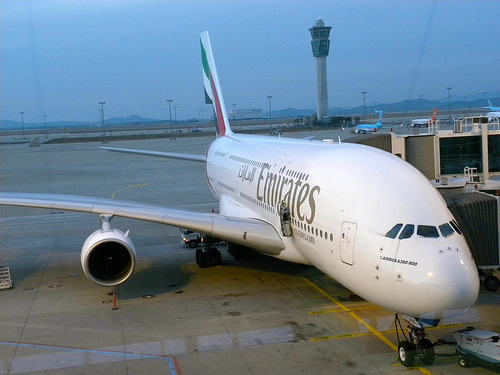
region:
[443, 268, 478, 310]
nose of the airplane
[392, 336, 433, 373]
wheels in front of airplane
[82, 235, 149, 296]
engine on the airplane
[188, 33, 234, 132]
tail part of airplane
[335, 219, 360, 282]
door on the airplane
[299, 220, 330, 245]
windows on side of plane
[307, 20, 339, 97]
the air traffic tower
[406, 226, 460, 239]
windows in front of plane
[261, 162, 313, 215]
name of aircraft carrier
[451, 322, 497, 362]
cart for transporting luggage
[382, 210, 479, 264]
five dark air plane windows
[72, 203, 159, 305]
white air plane engine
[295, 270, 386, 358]
yellow painted lines on the grown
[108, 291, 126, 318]
orange night visible stick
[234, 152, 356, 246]
black letters on an airplane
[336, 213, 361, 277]
front door of an airplane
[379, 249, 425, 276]
letters and numbers on front of plane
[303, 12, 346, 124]
airport black watch tower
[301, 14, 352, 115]
control center of airport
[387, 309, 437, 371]
two black airplane wheels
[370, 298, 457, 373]
front landing gear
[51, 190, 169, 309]
cylindrical jet engine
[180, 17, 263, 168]
green, red and black markings on the tail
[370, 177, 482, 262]
cockpit windows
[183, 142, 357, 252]
two rows of passenger windows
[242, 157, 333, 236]
Emirates written on the airplane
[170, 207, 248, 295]
rear landing gear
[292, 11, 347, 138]
tall control tower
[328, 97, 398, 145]
blue airplane on the ground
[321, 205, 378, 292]
door on the side of the plane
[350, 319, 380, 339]
yellow paint on runway.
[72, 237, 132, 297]
engine of the plane.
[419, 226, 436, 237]
window on front of plane.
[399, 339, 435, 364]
front wheels of plane.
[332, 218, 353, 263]
door to the plane.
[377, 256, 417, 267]
writing on front of plane.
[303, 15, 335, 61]
top of control tower.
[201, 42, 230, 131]
tail of the airplane.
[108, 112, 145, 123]
hills in the distance.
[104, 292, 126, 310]
orange cone on tarmac.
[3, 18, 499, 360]
An airplane in the foreground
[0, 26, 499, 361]
Airplane is white in color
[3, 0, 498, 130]
The sky is cloudy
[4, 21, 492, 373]
Plane is on the ground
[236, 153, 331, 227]
Airplane has wording on the side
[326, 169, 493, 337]
A front view of an airplane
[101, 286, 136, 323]
A cone is on the ground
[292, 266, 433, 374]
A yellow line is on the ground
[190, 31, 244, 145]
Tail of the airplane is striped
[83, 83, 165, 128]
Small mountain is in the background